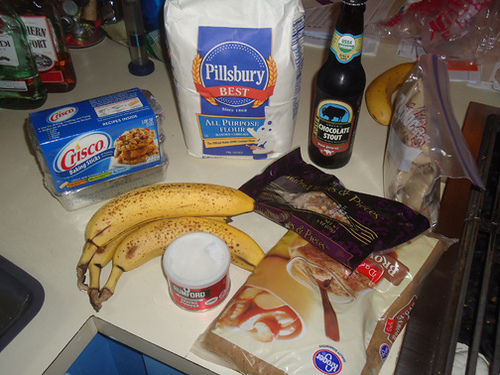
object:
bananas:
[96, 217, 268, 305]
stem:
[76, 234, 107, 296]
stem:
[97, 266, 121, 302]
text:
[204, 63, 266, 86]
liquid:
[14, 2, 80, 96]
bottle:
[306, 1, 370, 171]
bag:
[237, 145, 433, 272]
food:
[235, 143, 434, 275]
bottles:
[0, 0, 51, 112]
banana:
[76, 180, 261, 291]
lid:
[162, 231, 236, 291]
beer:
[308, 0, 369, 171]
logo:
[312, 341, 352, 374]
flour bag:
[162, 0, 306, 162]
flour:
[164, 0, 310, 161]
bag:
[381, 52, 489, 238]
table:
[0, 33, 499, 374]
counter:
[0, 37, 499, 374]